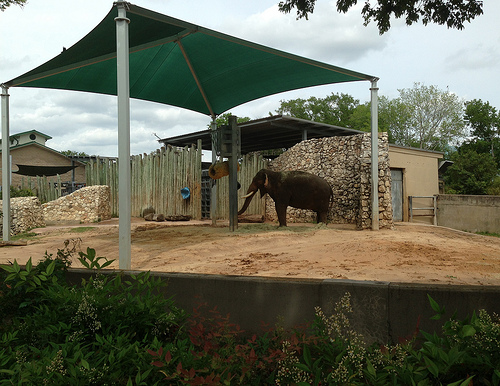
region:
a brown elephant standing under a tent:
[235, 167, 337, 227]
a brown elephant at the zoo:
[237, 166, 334, 224]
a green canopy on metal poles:
[0, 0, 380, 265]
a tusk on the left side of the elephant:
[238, 190, 255, 202]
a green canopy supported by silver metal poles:
[2, 0, 382, 268]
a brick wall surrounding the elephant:
[2, 262, 497, 373]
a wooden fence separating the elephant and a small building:
[86, 144, 202, 219]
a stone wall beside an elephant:
[267, 132, 389, 224]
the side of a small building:
[390, 141, 447, 226]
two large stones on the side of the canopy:
[0, 185, 112, 230]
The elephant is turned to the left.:
[237, 161, 344, 235]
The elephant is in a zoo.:
[27, 95, 459, 352]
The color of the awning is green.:
[150, 36, 275, 104]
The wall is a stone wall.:
[304, 142, 376, 183]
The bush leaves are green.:
[60, 290, 155, 342]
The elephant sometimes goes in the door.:
[380, 155, 415, 224]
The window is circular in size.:
[26, 127, 39, 147]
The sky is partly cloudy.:
[350, 31, 487, 81]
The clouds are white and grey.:
[255, 4, 379, 56]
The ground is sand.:
[253, 241, 351, 263]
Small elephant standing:
[246, 169, 335, 229]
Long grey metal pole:
[116, 16, 136, 272]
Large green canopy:
[103, 13, 251, 105]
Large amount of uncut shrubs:
[35, 292, 234, 367]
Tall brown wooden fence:
[136, 146, 201, 216]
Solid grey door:
[388, 165, 406, 222]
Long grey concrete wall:
[224, 283, 319, 330]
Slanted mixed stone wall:
[52, 181, 114, 221]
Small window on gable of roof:
[28, 132, 36, 140]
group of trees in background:
[441, 94, 494, 181]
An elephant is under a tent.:
[210, 153, 360, 249]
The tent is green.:
[0, 0, 393, 131]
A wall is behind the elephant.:
[224, 125, 407, 242]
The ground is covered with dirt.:
[34, 217, 489, 281]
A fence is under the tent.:
[45, 129, 217, 235]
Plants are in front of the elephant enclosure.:
[1, 292, 497, 384]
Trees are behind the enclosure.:
[281, 79, 497, 203]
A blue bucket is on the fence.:
[166, 180, 204, 205]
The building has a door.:
[374, 158, 421, 228]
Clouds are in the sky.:
[245, 11, 391, 66]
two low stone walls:
[1, 183, 113, 231]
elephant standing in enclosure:
[238, 166, 333, 229]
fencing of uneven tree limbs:
[83, 140, 203, 222]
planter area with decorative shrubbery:
[2, 236, 498, 384]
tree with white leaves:
[388, 80, 482, 156]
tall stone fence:
[263, 131, 394, 231]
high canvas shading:
[1, 1, 381, 271]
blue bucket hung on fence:
[178, 185, 192, 202]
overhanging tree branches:
[277, 1, 487, 37]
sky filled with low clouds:
[0, 1, 498, 158]